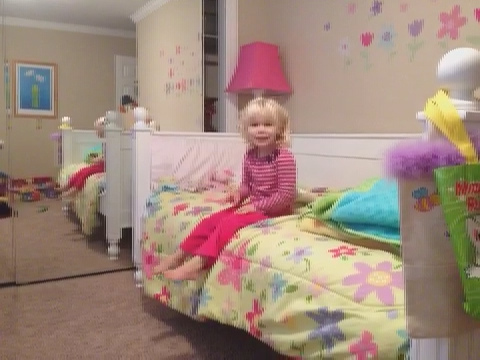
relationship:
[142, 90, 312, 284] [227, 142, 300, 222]
child wearing shirt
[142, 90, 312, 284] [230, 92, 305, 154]
child has hair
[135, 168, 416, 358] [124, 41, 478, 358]
blanket on bed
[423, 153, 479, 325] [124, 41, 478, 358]
bag on bed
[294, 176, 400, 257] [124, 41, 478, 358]
blanket on bed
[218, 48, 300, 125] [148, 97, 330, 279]
lamp behind girl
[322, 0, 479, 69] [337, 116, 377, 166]
flowers stickers on wall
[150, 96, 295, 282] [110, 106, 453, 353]
child sitting on bed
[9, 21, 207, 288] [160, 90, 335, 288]
mirror behind girl